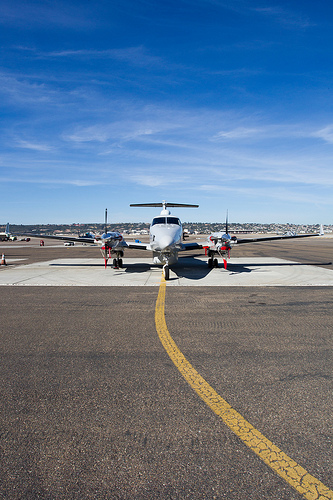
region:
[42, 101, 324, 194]
Light clouds in the sky.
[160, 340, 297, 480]
Yellow line on the ground.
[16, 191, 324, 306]
Plane in front of the camera.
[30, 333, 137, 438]
The ground is grey.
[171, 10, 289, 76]
The sky is blue.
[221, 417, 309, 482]
Cracks in the yellow line.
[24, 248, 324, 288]
White cement where the plane is.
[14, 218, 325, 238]
Hill in the background.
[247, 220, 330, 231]
Houses on the hill.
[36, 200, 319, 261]
The plane is mostly white.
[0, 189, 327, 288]
The airplane is on the ground.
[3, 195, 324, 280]
The plane is a jet.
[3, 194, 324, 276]
The plane is silver.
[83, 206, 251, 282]
The plane has two front engines.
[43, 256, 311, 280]
The plane's shadow is on the ground.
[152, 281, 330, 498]
A yellow stripe is on the ground.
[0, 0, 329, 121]
The sky is blue.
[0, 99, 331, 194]
Wispy clouds are in the sky.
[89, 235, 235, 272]
The plane has red parts.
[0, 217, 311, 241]
Trees are behind the airport.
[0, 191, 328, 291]
an airplane sits on the runway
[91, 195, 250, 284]
it has two propellers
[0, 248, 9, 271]
an orange safety cone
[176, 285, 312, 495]
a yellow stripe on the runway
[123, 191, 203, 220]
the tail section of the plane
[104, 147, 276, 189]
the sky is clear & blue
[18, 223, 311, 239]
it appears there is a town in the background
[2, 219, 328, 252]
the flaps are up on the plane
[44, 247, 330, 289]
the plane is casting a shadow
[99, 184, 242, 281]
the plane is mostly white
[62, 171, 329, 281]
airplane on a runway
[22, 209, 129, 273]
wings of a helicopter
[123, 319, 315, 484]
yellow painted stripe on runway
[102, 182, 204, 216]
helicopter blades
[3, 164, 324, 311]
helicpter on runway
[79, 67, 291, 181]
blue sky with some clouds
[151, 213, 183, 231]
front windows of helicopter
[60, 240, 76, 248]
car on runway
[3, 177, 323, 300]
helicopter with red and blue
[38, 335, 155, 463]
patch of asphalt on runway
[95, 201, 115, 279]
the propeller on an airplane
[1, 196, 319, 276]
an airplane on the tarmac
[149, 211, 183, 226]
the front windows of an airplane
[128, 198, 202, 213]
the tail of an airplane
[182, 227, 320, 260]
the wing of an airplane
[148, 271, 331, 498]
a yellow stripe on the tarmac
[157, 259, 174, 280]
the front wheel of an airplane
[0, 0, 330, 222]
a blue cloudy sky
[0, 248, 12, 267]
an orange and white striped cone on the tarmac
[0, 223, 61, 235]
a tree covered hillside in the distance